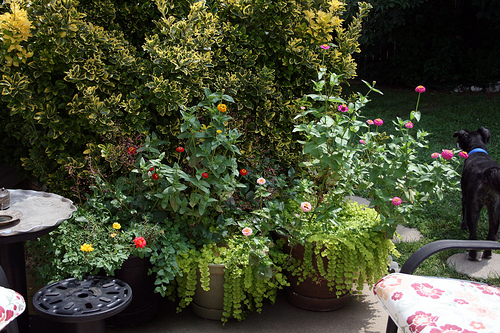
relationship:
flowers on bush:
[429, 149, 468, 166] [358, 84, 469, 224]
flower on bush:
[133, 234, 147, 249] [52, 209, 191, 295]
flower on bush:
[79, 241, 96, 255] [52, 209, 191, 295]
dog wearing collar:
[450, 125, 500, 261] [465, 145, 489, 158]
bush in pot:
[52, 209, 191, 295] [84, 257, 158, 326]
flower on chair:
[411, 278, 445, 300] [372, 237, 499, 331]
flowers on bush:
[364, 115, 386, 129] [358, 84, 469, 224]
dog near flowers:
[450, 125, 500, 261] [429, 149, 468, 166]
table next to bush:
[0, 186, 78, 332] [52, 209, 191, 295]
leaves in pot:
[148, 228, 184, 295] [84, 257, 158, 326]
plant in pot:
[310, 201, 399, 297] [282, 240, 354, 315]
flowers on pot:
[429, 149, 468, 166] [282, 240, 354, 315]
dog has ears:
[450, 125, 500, 261] [451, 126, 491, 140]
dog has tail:
[450, 125, 500, 261] [481, 163, 499, 194]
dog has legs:
[450, 125, 500, 261] [456, 197, 499, 262]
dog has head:
[450, 125, 500, 261] [451, 125, 490, 151]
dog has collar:
[450, 125, 500, 261] [465, 145, 489, 158]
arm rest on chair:
[402, 238, 499, 273] [372, 237, 499, 331]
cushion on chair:
[373, 273, 500, 331] [372, 237, 499, 331]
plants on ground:
[0, 0, 470, 320] [49, 279, 409, 332]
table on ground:
[0, 186, 78, 332] [49, 279, 409, 332]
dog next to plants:
[450, 125, 500, 261] [0, 0, 470, 320]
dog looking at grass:
[450, 125, 500, 261] [363, 80, 498, 281]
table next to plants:
[0, 186, 78, 332] [0, 0, 470, 320]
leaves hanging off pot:
[148, 228, 184, 295] [84, 257, 158, 326]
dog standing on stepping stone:
[450, 125, 500, 261] [447, 250, 499, 279]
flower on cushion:
[411, 278, 445, 300] [373, 273, 500, 331]